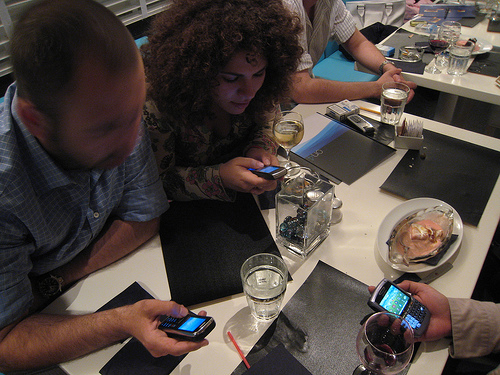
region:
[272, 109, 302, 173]
Glass filled with wine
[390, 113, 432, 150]
Small box with salt and pepper packets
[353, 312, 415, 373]
Big wine glass with a little red wine at bottom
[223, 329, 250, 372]
Small red straw on the table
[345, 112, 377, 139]
Cellphone on the table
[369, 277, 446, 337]
Cell phone open revealing apps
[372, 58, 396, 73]
A watch on a mans arm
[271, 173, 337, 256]
Square glass with marbles inside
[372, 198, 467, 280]
Small white plate of fish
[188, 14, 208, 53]
woman with curly hair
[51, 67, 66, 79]
man with black hair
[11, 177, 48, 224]
man wearing plaid shirt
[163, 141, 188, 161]
woman wearing flower jacket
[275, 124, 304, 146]
wine in wine glass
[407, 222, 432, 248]
pink custard in dish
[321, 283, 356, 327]
black mat on table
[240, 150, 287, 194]
woman with phone in hand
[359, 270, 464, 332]
man with phone in hand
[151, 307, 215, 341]
cell phone in man's hand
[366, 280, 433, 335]
cell phone in person's hand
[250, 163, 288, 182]
cell phone in woman's hand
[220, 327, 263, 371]
red straw on table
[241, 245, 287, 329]
glass of water on table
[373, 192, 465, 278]
pancakes on a plate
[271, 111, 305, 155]
wine glass on table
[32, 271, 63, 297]
watch on person's wrist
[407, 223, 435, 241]
butter on the pancakes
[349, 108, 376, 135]
phone on the table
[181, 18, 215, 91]
Person has brown hair.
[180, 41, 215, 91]
Person has curly hair.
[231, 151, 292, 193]
Person holding cell phone.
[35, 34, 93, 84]
Person has short hair.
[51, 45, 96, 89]
Person has dark hair.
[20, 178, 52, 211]
Person wearing blue and white shirt.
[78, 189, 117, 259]
Person wearing button down shirt.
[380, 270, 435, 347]
Person holding cell phone.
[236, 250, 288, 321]
a clear glass of water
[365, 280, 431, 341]
the phone is being used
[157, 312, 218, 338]
the phone is black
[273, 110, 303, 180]
a glass of wine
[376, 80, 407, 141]
a glass of water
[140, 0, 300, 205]
the woman has puffy hair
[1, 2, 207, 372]
the man is shaking his head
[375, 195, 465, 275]
a plate of food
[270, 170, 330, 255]
a clear glass container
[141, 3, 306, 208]
the lady is looking at a phone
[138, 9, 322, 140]
the girl's hair isa curly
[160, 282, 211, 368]
the phone is on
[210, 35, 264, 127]
the face of a woman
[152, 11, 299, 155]
the head of a woman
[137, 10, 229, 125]
the hair of a woman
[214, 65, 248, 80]
the eyebrow of a woman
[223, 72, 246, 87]
the eye of a woman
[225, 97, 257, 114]
the lips of a woman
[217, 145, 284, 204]
the hands of a woman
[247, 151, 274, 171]
the thumbs of a woman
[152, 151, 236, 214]
the sleeve of a woman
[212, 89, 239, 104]
the cheek of a woman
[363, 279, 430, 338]
the blackberry phone in the plam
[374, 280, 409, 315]
the screen on the phone